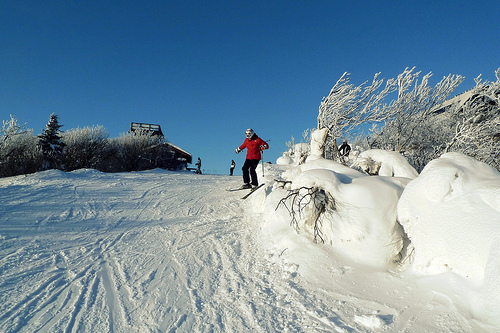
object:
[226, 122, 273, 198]
skier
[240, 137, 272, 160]
jacket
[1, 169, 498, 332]
snow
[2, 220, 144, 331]
tracks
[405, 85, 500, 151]
house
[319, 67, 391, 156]
trees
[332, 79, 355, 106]
snow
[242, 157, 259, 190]
pants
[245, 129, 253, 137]
helmet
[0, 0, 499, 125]
sky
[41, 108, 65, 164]
tree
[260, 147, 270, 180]
pole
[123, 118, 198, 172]
resort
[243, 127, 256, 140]
head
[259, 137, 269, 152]
arm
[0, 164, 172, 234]
shadows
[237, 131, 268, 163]
coat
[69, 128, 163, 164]
snow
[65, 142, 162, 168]
bush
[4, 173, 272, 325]
ground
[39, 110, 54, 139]
snow